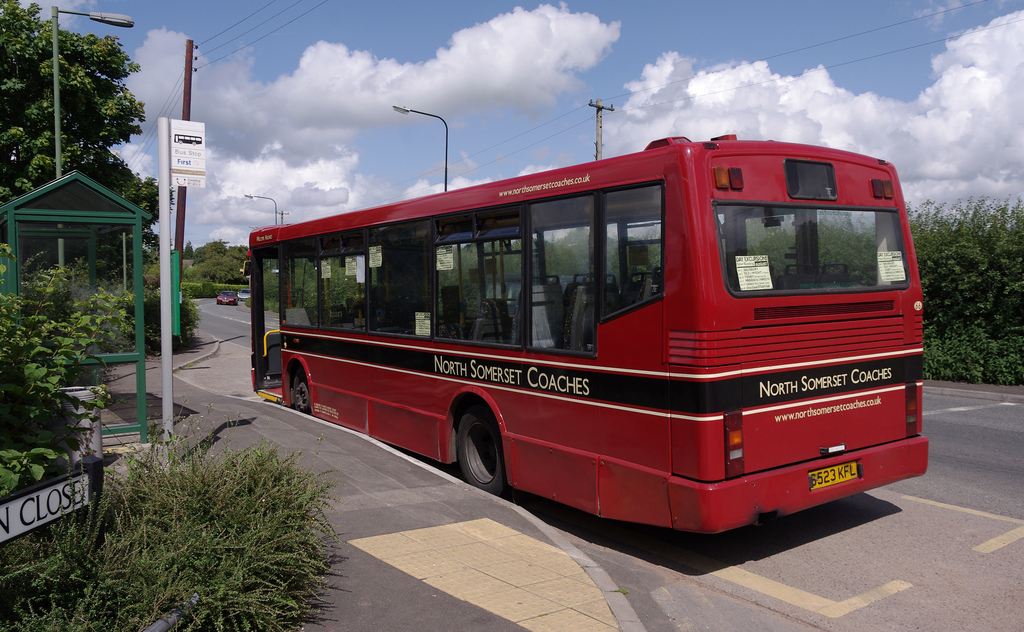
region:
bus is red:
[247, 135, 933, 540]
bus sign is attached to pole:
[155, 117, 207, 487]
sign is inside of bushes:
[0, 452, 108, 548]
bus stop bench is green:
[2, 173, 157, 450]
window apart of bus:
[714, 195, 915, 294]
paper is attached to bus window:
[736, 250, 772, 293]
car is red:
[217, 284, 240, 307]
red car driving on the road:
[215, 287, 238, 307]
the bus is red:
[227, 119, 958, 575]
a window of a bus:
[507, 165, 684, 380]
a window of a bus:
[431, 217, 531, 358]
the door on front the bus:
[243, 230, 298, 411]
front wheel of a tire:
[273, 350, 322, 421]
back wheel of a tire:
[439, 382, 531, 493]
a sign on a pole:
[145, 100, 219, 203]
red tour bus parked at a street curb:
[247, 130, 928, 536]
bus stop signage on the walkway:
[147, 113, 212, 445]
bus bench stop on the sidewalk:
[0, 165, 155, 451]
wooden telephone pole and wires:
[168, 0, 315, 117]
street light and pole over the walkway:
[40, 0, 140, 168]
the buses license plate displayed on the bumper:
[802, 453, 863, 496]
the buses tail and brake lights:
[717, 399, 750, 482]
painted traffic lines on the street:
[713, 499, 1021, 630]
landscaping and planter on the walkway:
[2, 372, 320, 630]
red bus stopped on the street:
[230, 123, 921, 541]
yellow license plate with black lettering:
[803, 458, 858, 491]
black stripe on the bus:
[282, 330, 927, 439]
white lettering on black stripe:
[429, 345, 897, 416]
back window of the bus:
[708, 191, 904, 291]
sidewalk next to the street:
[154, 320, 617, 630]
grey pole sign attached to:
[158, 123, 187, 462]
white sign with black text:
[165, 121, 211, 194]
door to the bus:
[250, 262, 285, 390]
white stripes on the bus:
[279, 324, 934, 420]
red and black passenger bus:
[206, 142, 963, 569]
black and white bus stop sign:
[140, 98, 233, 419]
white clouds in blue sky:
[244, 22, 320, 83]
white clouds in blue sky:
[323, 23, 385, 91]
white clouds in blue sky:
[645, 43, 715, 100]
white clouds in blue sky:
[768, 29, 835, 86]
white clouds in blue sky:
[944, 72, 987, 139]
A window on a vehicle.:
[593, 184, 667, 324]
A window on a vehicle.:
[515, 200, 608, 371]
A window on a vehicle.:
[524, 194, 616, 365]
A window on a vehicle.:
[277, 232, 322, 325]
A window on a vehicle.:
[326, 241, 380, 339]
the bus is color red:
[220, 123, 947, 559]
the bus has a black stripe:
[232, 320, 936, 435]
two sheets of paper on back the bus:
[721, 238, 916, 302]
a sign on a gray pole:
[142, 103, 214, 426]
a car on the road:
[201, 267, 251, 321]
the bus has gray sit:
[503, 261, 579, 374]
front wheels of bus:
[271, 353, 319, 423]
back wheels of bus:
[442, 384, 518, 504]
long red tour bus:
[211, 133, 936, 571]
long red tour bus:
[236, 113, 944, 585]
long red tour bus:
[230, 124, 948, 573]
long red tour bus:
[224, 124, 949, 574]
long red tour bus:
[217, 124, 944, 559]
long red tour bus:
[229, 121, 961, 567]